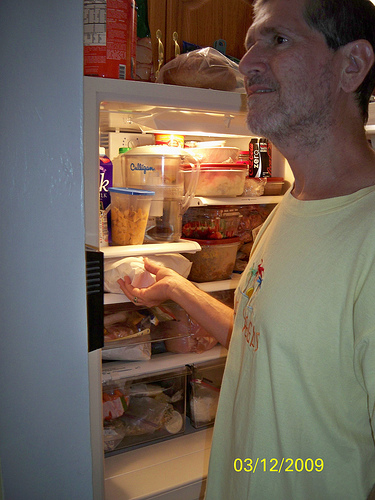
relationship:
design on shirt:
[230, 253, 270, 351] [205, 156, 373, 497]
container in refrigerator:
[121, 150, 191, 242] [38, 46, 248, 452]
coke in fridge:
[239, 120, 294, 195] [92, 109, 351, 338]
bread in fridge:
[147, 38, 242, 90] [77, 60, 301, 497]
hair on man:
[246, 70, 347, 162] [203, 1, 373, 495]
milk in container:
[128, 140, 170, 217] [122, 146, 169, 228]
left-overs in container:
[110, 205, 150, 246] [109, 186, 155, 246]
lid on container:
[184, 233, 257, 245] [183, 231, 244, 281]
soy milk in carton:
[98, 146, 115, 248] [97, 142, 109, 247]